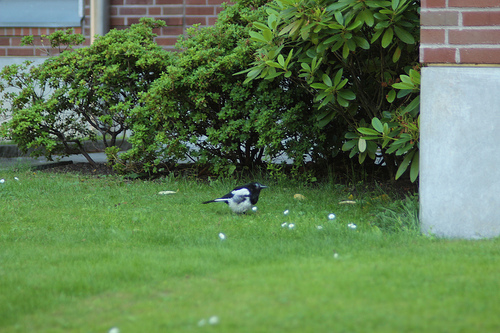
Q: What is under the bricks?
A: Concrete.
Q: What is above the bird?
A: Green bushes.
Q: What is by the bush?
A: Corner of building.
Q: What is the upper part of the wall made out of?
A: Brick.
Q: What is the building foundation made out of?
A: Cement.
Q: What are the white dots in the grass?
A: Flowers.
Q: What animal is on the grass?
A: Bird.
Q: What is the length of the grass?
A: Short.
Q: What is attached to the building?
A: Silver pipe.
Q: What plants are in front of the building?
A: Bushes.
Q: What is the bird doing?
A: Observing.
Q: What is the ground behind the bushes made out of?
A: Cement.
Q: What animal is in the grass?
A: Black and white bird.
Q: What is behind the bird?
A: Bushes.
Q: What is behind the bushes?
A: Brick walls.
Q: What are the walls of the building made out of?
A: Bricks.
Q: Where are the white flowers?
A: In the grass.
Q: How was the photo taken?
A: With a telephoto lens.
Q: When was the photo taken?
A: Last week.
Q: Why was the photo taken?
A: For a magazine.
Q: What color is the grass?
A: Green.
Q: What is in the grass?
A: A bird.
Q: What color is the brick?
A: Red.